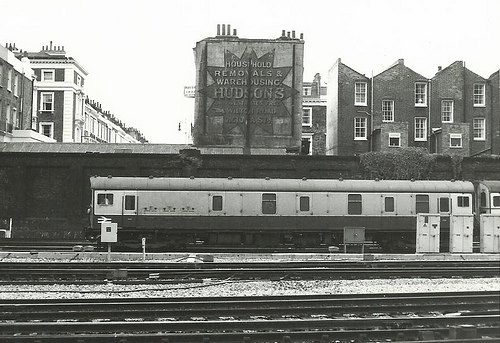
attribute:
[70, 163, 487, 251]
train — two-toned, moving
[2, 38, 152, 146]
background — distant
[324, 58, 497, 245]
building — multi story brick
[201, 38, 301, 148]
building — old 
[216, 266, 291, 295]
gravel — light gray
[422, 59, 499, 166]
building — brick, multi story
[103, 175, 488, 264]
train — old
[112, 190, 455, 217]
windows — round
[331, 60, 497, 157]
building — multi story, brick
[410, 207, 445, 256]
power box — three 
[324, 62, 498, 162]
housing complex — distant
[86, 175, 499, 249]
train — long, white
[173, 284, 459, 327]
tracks — train